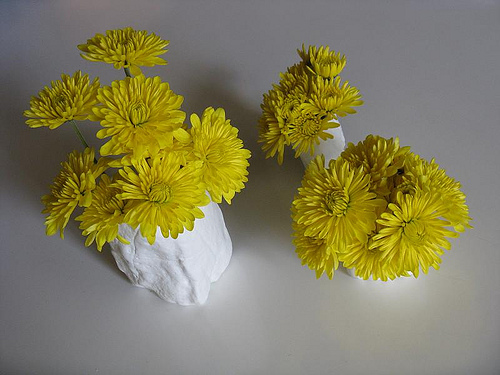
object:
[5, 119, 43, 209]
shadow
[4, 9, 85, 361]
table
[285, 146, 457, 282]
flowers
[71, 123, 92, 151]
stem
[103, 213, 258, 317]
vase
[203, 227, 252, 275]
clay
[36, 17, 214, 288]
bunch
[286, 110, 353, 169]
vase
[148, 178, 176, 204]
center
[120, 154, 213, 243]
flower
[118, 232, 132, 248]
petal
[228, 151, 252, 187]
petals